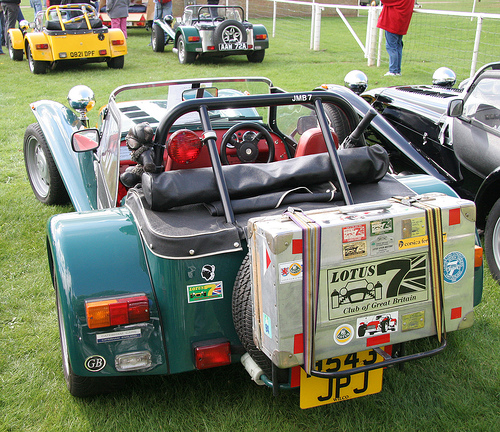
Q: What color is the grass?
A: Green.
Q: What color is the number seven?
A: Black.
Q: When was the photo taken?
A: Daytime.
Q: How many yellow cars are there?
A: One.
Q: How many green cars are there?
A: Two.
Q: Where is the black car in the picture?
A: Next to the green car.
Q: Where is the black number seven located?
A: Behind the green car.